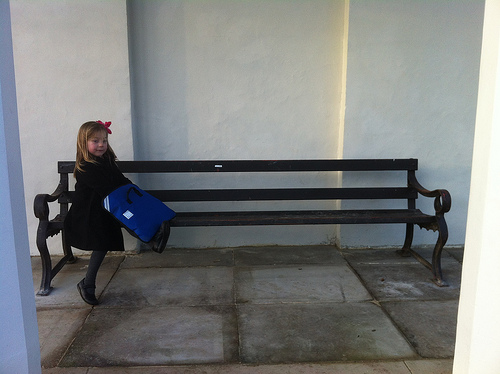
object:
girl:
[63, 120, 171, 305]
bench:
[32, 159, 451, 297]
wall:
[9, 1, 488, 256]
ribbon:
[96, 120, 113, 135]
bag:
[99, 182, 177, 243]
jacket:
[61, 157, 131, 252]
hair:
[72, 120, 118, 175]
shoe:
[76, 276, 99, 305]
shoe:
[149, 221, 169, 254]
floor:
[28, 244, 464, 371]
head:
[79, 122, 107, 158]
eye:
[94, 140, 99, 143]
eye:
[103, 140, 106, 143]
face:
[87, 134, 108, 157]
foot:
[75, 277, 99, 306]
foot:
[149, 219, 171, 254]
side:
[8, 0, 148, 255]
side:
[336, 1, 486, 248]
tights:
[83, 245, 106, 289]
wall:
[1, 1, 43, 372]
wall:
[451, 1, 498, 373]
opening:
[47, 200, 62, 219]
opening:
[415, 190, 438, 218]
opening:
[68, 173, 77, 191]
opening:
[122, 168, 410, 189]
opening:
[161, 197, 411, 213]